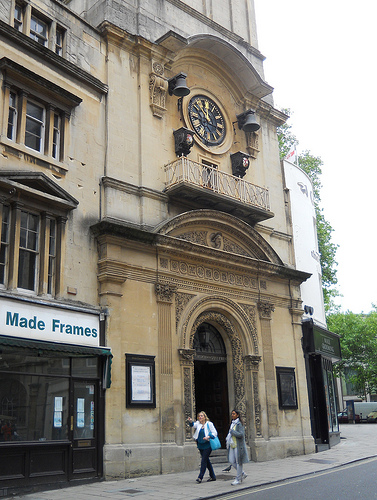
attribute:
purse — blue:
[205, 422, 220, 450]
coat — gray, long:
[231, 421, 246, 466]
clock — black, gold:
[184, 90, 233, 146]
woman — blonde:
[183, 410, 228, 486]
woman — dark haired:
[222, 412, 250, 486]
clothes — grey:
[225, 425, 249, 474]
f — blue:
[48, 311, 60, 331]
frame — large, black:
[124, 349, 156, 409]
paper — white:
[128, 363, 149, 401]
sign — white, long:
[2, 299, 103, 346]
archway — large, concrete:
[163, 289, 267, 353]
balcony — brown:
[165, 160, 274, 224]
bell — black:
[170, 72, 191, 96]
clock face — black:
[179, 86, 237, 151]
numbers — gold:
[187, 93, 228, 143]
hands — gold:
[191, 92, 214, 129]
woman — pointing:
[184, 407, 222, 478]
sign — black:
[277, 360, 298, 412]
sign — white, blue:
[0, 285, 104, 349]